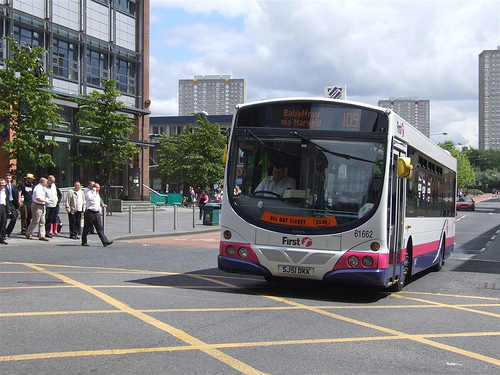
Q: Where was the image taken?
A: It was taken at the road.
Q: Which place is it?
A: It is a road.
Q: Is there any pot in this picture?
A: No, there are no pots.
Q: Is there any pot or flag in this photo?
A: No, there are no pots or flags.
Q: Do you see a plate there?
A: Yes, there is a plate.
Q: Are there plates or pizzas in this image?
A: Yes, there is a plate.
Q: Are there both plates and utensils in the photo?
A: No, there is a plate but no utensils.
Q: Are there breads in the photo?
A: No, there are no breads.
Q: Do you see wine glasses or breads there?
A: No, there are no breads or wine glasses.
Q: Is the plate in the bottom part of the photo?
A: Yes, the plate is in the bottom of the image.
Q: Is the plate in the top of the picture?
A: No, the plate is in the bottom of the image.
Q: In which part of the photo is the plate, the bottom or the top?
A: The plate is in the bottom of the image.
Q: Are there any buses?
A: Yes, there is a bus.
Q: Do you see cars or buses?
A: Yes, there is a bus.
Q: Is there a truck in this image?
A: No, there are no trucks.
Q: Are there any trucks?
A: No, there are no trucks.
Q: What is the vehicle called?
A: The vehicle is a bus.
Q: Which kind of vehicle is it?
A: The vehicle is a bus.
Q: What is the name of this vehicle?
A: This is a bus.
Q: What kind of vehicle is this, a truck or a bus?
A: This is a bus.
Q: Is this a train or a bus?
A: This is a bus.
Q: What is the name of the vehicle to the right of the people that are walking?
A: The vehicle is a bus.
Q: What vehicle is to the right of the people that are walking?
A: The vehicle is a bus.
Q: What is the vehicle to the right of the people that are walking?
A: The vehicle is a bus.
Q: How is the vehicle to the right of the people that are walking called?
A: The vehicle is a bus.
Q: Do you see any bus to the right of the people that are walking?
A: Yes, there is a bus to the right of the people.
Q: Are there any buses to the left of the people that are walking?
A: No, the bus is to the right of the people.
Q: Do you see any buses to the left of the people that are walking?
A: No, the bus is to the right of the people.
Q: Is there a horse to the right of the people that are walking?
A: No, there is a bus to the right of the people.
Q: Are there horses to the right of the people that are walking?
A: No, there is a bus to the right of the people.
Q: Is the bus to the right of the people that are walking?
A: Yes, the bus is to the right of the people.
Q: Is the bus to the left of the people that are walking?
A: No, the bus is to the right of the people.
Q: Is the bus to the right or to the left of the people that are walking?
A: The bus is to the right of the people.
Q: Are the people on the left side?
A: Yes, the people are on the left of the image.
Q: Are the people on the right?
A: No, the people are on the left of the image.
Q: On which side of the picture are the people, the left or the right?
A: The people are on the left of the image.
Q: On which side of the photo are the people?
A: The people are on the left of the image.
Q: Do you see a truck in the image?
A: No, there are no trucks.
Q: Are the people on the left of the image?
A: Yes, the people are on the left of the image.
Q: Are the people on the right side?
A: No, the people are on the left of the image.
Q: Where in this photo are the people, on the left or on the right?
A: The people are on the left of the image.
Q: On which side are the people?
A: The people are on the left of the image.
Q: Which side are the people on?
A: The people are on the left of the image.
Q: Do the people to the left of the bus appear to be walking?
A: Yes, the people are walking.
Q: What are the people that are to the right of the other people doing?
A: The people are walking.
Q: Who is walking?
A: The people are walking.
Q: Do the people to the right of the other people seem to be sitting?
A: No, the people are walking.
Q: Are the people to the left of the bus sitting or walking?
A: The people are walking.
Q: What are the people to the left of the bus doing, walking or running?
A: The people are walking.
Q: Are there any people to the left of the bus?
A: Yes, there are people to the left of the bus.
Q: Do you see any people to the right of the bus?
A: No, the people are to the left of the bus.